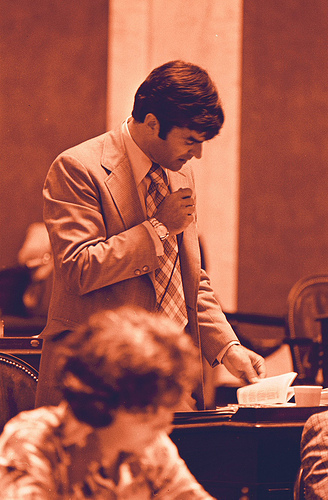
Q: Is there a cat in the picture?
A: No, there are no cats.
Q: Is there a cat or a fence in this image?
A: No, there are no cats or fences.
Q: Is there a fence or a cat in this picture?
A: No, there are no cats or fences.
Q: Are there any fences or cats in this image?
A: No, there are no cats or fences.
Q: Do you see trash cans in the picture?
A: No, there are no trash cans.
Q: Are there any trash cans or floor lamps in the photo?
A: No, there are no trash cans or floor lamps.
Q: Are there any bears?
A: No, there are no bears.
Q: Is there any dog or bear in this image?
A: No, there are no bears or dogs.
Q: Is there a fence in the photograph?
A: No, there are no fences.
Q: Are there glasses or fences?
A: No, there are no fences or glasses.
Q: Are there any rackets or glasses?
A: No, there are no glasses or rackets.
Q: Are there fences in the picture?
A: No, there are no fences.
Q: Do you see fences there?
A: No, there are no fences.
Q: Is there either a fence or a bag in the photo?
A: No, there are no fences or bags.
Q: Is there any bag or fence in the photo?
A: No, there are no fences or bags.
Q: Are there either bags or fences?
A: No, there are no fences or bags.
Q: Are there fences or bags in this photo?
A: No, there are no fences or bags.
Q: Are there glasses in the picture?
A: No, there are no glasses.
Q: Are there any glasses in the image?
A: No, there are no glasses.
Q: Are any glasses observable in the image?
A: No, there are no glasses.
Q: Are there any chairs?
A: Yes, there is a chair.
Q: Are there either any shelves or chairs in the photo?
A: Yes, there is a chair.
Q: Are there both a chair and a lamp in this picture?
A: No, there is a chair but no lamps.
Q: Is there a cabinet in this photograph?
A: No, there are no cabinets.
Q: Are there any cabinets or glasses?
A: No, there are no cabinets or glasses.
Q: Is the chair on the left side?
A: Yes, the chair is on the left of the image.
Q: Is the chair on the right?
A: No, the chair is on the left of the image.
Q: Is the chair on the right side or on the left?
A: The chair is on the left of the image.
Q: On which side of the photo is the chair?
A: The chair is on the left of the image.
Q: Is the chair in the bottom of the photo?
A: Yes, the chair is in the bottom of the image.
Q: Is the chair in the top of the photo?
A: No, the chair is in the bottom of the image.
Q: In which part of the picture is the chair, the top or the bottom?
A: The chair is in the bottom of the image.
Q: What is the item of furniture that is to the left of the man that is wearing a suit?
A: The piece of furniture is a chair.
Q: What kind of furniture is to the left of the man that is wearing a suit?
A: The piece of furniture is a chair.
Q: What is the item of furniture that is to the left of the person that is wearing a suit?
A: The piece of furniture is a chair.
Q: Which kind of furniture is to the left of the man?
A: The piece of furniture is a chair.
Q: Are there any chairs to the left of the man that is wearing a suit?
A: Yes, there is a chair to the left of the man.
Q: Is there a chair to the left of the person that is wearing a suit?
A: Yes, there is a chair to the left of the man.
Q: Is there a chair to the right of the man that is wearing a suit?
A: No, the chair is to the left of the man.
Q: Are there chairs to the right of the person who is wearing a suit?
A: No, the chair is to the left of the man.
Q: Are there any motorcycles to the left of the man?
A: No, there is a chair to the left of the man.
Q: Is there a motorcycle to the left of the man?
A: No, there is a chair to the left of the man.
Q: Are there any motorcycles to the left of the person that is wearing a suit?
A: No, there is a chair to the left of the man.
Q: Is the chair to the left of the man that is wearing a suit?
A: Yes, the chair is to the left of the man.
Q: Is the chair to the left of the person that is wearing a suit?
A: Yes, the chair is to the left of the man.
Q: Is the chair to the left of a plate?
A: No, the chair is to the left of the man.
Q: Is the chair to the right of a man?
A: No, the chair is to the left of a man.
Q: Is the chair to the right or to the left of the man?
A: The chair is to the left of the man.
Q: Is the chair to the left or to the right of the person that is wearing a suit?
A: The chair is to the left of the man.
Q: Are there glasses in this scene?
A: No, there are no glasses.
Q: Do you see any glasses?
A: No, there are no glasses.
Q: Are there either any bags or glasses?
A: No, there are no glasses or bags.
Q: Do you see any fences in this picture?
A: No, there are no fences.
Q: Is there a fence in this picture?
A: No, there are no fences.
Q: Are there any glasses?
A: No, there are no glasses.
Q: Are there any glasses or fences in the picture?
A: No, there are no glasses or fences.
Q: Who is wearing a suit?
A: The man is wearing a suit.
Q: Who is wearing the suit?
A: The man is wearing a suit.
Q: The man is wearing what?
A: The man is wearing a suit.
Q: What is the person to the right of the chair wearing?
A: The man is wearing a suit.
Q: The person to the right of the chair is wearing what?
A: The man is wearing a suit.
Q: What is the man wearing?
A: The man is wearing a suit.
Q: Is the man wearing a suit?
A: Yes, the man is wearing a suit.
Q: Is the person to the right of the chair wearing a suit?
A: Yes, the man is wearing a suit.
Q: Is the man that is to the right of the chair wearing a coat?
A: No, the man is wearing a suit.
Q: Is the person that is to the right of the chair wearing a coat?
A: No, the man is wearing a suit.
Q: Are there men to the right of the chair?
A: Yes, there is a man to the right of the chair.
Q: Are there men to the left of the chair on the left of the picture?
A: No, the man is to the right of the chair.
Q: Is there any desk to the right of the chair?
A: No, there is a man to the right of the chair.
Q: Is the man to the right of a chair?
A: Yes, the man is to the right of a chair.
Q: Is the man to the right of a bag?
A: No, the man is to the right of a chair.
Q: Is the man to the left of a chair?
A: No, the man is to the right of a chair.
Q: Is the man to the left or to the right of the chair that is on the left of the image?
A: The man is to the right of the chair.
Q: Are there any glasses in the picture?
A: No, there are no glasses.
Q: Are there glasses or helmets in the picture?
A: No, there are no glasses or helmets.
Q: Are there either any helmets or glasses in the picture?
A: No, there are no glasses or helmets.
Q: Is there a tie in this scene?
A: Yes, there is a tie.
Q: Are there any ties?
A: Yes, there is a tie.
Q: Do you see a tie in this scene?
A: Yes, there is a tie.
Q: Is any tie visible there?
A: Yes, there is a tie.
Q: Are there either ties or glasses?
A: Yes, there is a tie.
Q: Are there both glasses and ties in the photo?
A: No, there is a tie but no glasses.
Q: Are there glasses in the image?
A: No, there are no glasses.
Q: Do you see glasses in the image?
A: No, there are no glasses.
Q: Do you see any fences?
A: No, there are no fences.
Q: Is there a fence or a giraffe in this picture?
A: No, there are no fences or giraffes.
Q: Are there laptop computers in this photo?
A: No, there are no laptop computers.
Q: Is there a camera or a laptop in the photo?
A: No, there are no laptops or cameras.